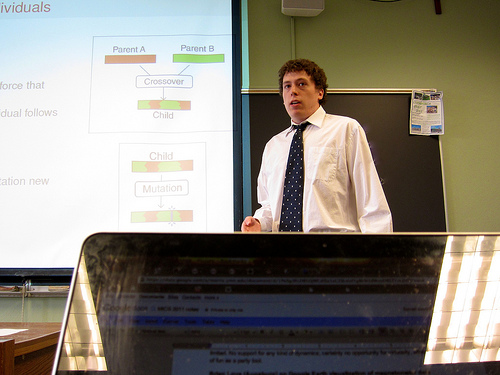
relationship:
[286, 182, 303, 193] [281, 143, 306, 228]
dots on tie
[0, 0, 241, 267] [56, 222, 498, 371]
information on laptop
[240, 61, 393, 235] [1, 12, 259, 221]
guy by screen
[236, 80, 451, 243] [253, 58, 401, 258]
blackboard behind man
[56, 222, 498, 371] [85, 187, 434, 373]
laptop in foreground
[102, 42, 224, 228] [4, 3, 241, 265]
graph on screen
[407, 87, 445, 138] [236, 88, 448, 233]
paper on blackboard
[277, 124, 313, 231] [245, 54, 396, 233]
tie on man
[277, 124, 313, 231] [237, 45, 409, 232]
tie on guy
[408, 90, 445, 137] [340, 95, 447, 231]
poster attached to chalkboard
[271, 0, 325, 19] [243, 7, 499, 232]
speaker box mounted to wall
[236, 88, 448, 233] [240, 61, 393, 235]
blackboard behind guy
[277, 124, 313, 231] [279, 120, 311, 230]
tie with spots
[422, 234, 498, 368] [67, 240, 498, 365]
light reflected on laptop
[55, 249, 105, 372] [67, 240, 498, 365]
light reflected on laptop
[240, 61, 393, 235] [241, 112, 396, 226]
guy in shirt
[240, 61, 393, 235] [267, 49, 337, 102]
guy with hair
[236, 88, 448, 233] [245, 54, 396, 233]
blackboard behind man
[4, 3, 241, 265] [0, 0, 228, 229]
screen with spreadsheet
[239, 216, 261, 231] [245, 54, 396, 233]
right hand of man